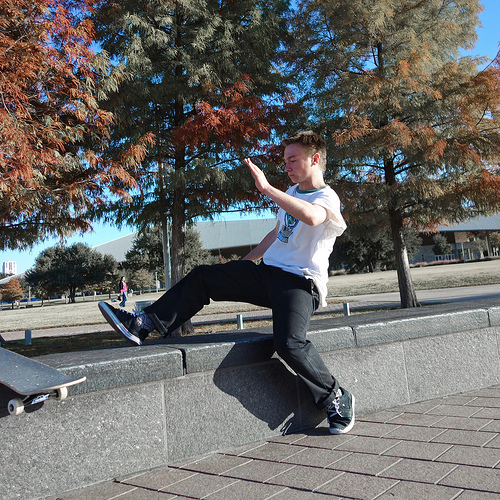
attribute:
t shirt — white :
[259, 174, 356, 306]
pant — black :
[130, 257, 348, 415]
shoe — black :
[94, 302, 360, 437]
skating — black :
[3, 346, 98, 423]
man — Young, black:
[94, 127, 372, 438]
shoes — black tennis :
[94, 300, 360, 438]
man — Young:
[76, 119, 363, 442]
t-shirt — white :
[250, 177, 349, 304]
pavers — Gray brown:
[240, 443, 467, 482]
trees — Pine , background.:
[7, 10, 483, 195]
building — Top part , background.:
[1, 244, 20, 280]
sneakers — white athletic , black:
[88, 293, 364, 441]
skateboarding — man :
[0, 340, 86, 427]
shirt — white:
[257, 185, 347, 301]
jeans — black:
[132, 259, 335, 408]